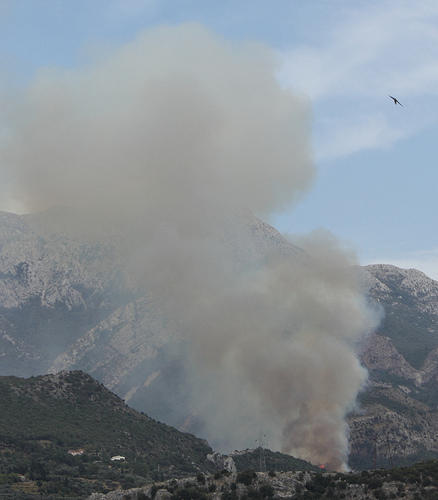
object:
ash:
[279, 372, 353, 470]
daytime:
[0, 0, 437, 500]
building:
[67, 447, 86, 456]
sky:
[1, 0, 437, 294]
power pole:
[366, 436, 381, 475]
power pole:
[384, 430, 398, 471]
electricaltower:
[253, 431, 269, 471]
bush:
[306, 475, 329, 493]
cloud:
[0, 0, 438, 283]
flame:
[318, 464, 324, 468]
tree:
[236, 469, 258, 487]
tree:
[248, 483, 274, 499]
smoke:
[0, 23, 380, 471]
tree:
[215, 466, 232, 479]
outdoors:
[1, 1, 437, 498]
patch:
[0, 285, 147, 377]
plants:
[84, 444, 95, 455]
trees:
[194, 472, 206, 495]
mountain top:
[0, 366, 438, 500]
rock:
[110, 453, 126, 463]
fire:
[318, 457, 325, 469]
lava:
[309, 455, 334, 479]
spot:
[147, 478, 165, 498]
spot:
[194, 470, 210, 485]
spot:
[235, 464, 256, 484]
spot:
[266, 466, 278, 477]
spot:
[291, 481, 305, 495]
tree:
[236, 459, 259, 490]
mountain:
[0, 366, 438, 500]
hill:
[0, 208, 438, 498]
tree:
[196, 472, 205, 484]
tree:
[75, 461, 97, 477]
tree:
[20, 458, 46, 480]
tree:
[150, 420, 166, 433]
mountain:
[1, 207, 438, 470]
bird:
[388, 93, 405, 110]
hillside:
[0, 367, 213, 480]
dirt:
[12, 369, 79, 405]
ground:
[58, 429, 174, 492]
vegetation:
[2, 366, 220, 497]